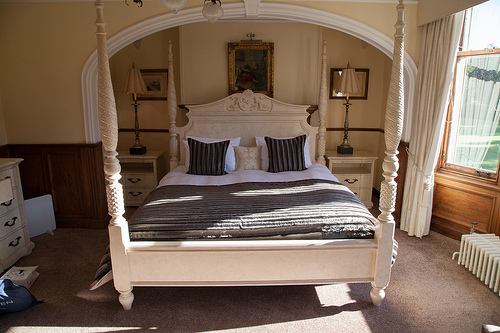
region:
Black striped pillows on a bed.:
[173, 127, 315, 175]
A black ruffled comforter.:
[148, 182, 373, 239]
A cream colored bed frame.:
[77, 10, 422, 310]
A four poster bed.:
[75, 7, 405, 304]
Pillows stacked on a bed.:
[180, 128, 322, 206]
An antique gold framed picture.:
[213, 32, 283, 108]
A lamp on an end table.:
[334, 63, 374, 190]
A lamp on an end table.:
[121, 58, 151, 168]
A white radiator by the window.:
[438, 221, 497, 291]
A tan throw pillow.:
[228, 140, 266, 172]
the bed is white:
[94, 41, 441, 276]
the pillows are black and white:
[258, 128, 311, 170]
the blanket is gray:
[173, 185, 325, 235]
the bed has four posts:
[75, 13, 420, 282]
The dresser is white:
[0, 147, 42, 262]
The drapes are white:
[392, 11, 464, 259]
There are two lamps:
[110, 55, 365, 153]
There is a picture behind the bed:
[225, 37, 274, 102]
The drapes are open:
[435, 20, 499, 177]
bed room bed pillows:
[178, 130, 313, 175]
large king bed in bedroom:
[138, 93, 364, 305]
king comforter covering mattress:
[142, 170, 373, 245]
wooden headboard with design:
[160, 33, 333, 176]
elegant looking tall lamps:
[331, 60, 361, 169]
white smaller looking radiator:
[450, 213, 496, 289]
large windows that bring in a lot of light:
[446, 38, 498, 194]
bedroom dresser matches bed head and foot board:
[1, 130, 32, 272]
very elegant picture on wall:
[218, 27, 286, 104]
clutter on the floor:
[0, 258, 52, 300]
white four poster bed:
[98, 5, 403, 308]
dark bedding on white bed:
[111, 95, 408, 312]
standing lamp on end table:
[327, 58, 363, 159]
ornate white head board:
[176, 88, 318, 140]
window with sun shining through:
[448, 50, 498, 187]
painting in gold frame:
[220, 35, 280, 102]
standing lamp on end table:
[114, 55, 157, 160]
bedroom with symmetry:
[73, 0, 410, 322]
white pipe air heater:
[450, 218, 497, 288]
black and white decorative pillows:
[175, 132, 320, 177]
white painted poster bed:
[93, 3, 405, 303]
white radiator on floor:
[460, 232, 499, 297]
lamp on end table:
[333, 65, 360, 155]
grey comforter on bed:
[133, 178, 375, 238]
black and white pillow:
[263, 134, 306, 171]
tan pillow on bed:
[234, 146, 263, 171]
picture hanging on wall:
[224, 39, 274, 96]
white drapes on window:
[403, 10, 467, 237]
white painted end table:
[327, 154, 377, 211]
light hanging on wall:
[194, 1, 226, 22]